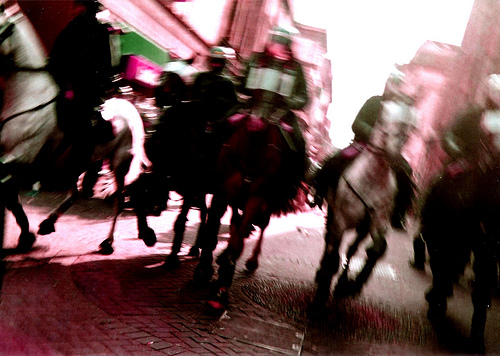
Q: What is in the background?
A: Buildings.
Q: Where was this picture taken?
A: Street.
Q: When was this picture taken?
A: Daytime.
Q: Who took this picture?
A: A photographer.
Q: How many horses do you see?
A: Over five.